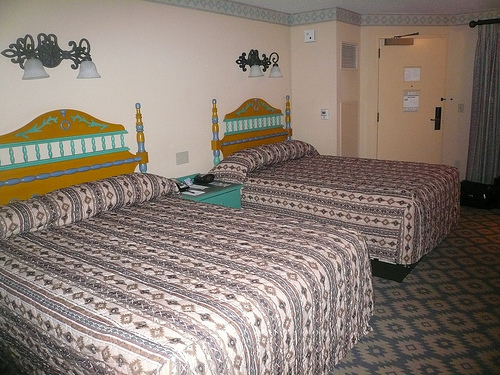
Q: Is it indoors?
A: Yes, it is indoors.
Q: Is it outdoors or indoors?
A: It is indoors.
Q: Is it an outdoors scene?
A: No, it is indoors.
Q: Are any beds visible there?
A: Yes, there is a bed.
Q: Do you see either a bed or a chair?
A: Yes, there is a bed.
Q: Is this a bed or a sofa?
A: This is a bed.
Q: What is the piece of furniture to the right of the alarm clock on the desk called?
A: The piece of furniture is a bed.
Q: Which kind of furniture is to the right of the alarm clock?
A: The piece of furniture is a bed.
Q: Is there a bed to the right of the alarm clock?
A: Yes, there is a bed to the right of the alarm clock.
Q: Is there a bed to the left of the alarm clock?
A: No, the bed is to the right of the alarm clock.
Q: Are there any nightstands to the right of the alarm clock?
A: No, there is a bed to the right of the alarm clock.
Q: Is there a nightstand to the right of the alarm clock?
A: No, there is a bed to the right of the alarm clock.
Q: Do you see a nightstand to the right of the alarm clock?
A: No, there is a bed to the right of the alarm clock.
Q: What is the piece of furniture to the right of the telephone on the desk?
A: The piece of furniture is a bed.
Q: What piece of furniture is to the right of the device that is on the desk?
A: The piece of furniture is a bed.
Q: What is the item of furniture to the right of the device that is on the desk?
A: The piece of furniture is a bed.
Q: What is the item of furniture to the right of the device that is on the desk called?
A: The piece of furniture is a bed.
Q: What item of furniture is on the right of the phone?
A: The piece of furniture is a bed.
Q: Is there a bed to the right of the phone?
A: Yes, there is a bed to the right of the phone.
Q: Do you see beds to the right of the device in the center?
A: Yes, there is a bed to the right of the phone.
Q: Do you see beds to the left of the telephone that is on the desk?
A: No, the bed is to the right of the telephone.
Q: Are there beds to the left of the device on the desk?
A: No, the bed is to the right of the telephone.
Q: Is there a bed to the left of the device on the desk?
A: No, the bed is to the right of the telephone.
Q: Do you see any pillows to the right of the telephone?
A: No, there is a bed to the right of the telephone.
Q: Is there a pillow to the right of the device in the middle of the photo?
A: No, there is a bed to the right of the telephone.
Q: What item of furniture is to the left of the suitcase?
A: The piece of furniture is a bed.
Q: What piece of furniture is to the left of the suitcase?
A: The piece of furniture is a bed.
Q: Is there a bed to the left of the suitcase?
A: Yes, there is a bed to the left of the suitcase.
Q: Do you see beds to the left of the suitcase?
A: Yes, there is a bed to the left of the suitcase.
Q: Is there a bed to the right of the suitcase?
A: No, the bed is to the left of the suitcase.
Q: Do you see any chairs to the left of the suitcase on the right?
A: No, there is a bed to the left of the suitcase.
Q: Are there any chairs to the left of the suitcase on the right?
A: No, there is a bed to the left of the suitcase.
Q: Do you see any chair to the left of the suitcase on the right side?
A: No, there is a bed to the left of the suitcase.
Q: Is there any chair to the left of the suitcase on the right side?
A: No, there is a bed to the left of the suitcase.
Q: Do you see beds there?
A: Yes, there is a bed.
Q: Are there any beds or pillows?
A: Yes, there is a bed.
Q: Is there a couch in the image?
A: No, there are no couches.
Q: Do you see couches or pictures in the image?
A: No, there are no couches or pictures.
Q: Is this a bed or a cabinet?
A: This is a bed.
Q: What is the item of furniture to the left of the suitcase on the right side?
A: The piece of furniture is a bed.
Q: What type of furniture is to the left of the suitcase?
A: The piece of furniture is a bed.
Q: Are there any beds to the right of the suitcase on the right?
A: No, the bed is to the left of the suitcase.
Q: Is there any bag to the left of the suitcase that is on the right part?
A: No, there is a bed to the left of the suitcase.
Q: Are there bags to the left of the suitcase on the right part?
A: No, there is a bed to the left of the suitcase.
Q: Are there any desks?
A: Yes, there is a desk.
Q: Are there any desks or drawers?
A: Yes, there is a desk.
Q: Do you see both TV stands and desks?
A: No, there is a desk but no TV stands.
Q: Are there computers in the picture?
A: No, there are no computers.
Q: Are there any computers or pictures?
A: No, there are no computers or pictures.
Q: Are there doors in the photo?
A: Yes, there is a door.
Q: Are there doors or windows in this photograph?
A: Yes, there is a door.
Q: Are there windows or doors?
A: Yes, there is a door.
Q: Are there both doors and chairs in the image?
A: No, there is a door but no chairs.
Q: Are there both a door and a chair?
A: No, there is a door but no chairs.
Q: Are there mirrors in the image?
A: No, there are no mirrors.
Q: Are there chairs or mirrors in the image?
A: No, there are no mirrors or chairs.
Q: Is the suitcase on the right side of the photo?
A: Yes, the suitcase is on the right of the image.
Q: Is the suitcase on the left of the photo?
A: No, the suitcase is on the right of the image.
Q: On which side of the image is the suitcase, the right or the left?
A: The suitcase is on the right of the image.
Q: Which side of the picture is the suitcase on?
A: The suitcase is on the right of the image.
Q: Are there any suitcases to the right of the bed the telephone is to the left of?
A: Yes, there is a suitcase to the right of the bed.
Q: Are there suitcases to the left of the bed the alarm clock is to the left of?
A: No, the suitcase is to the right of the bed.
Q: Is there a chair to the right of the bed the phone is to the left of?
A: No, there is a suitcase to the right of the bed.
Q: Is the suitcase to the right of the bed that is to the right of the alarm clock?
A: Yes, the suitcase is to the right of the bed.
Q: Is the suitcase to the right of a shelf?
A: No, the suitcase is to the right of the bed.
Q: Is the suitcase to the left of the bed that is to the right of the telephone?
A: No, the suitcase is to the right of the bed.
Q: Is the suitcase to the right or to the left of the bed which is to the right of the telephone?
A: The suitcase is to the right of the bed.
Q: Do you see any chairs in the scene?
A: No, there are no chairs.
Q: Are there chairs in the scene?
A: No, there are no chairs.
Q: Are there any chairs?
A: No, there are no chairs.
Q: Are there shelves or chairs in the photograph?
A: No, there are no chairs or shelves.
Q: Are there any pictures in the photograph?
A: No, there are no pictures.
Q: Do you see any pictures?
A: No, there are no pictures.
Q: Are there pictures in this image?
A: No, there are no pictures.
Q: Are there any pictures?
A: No, there are no pictures.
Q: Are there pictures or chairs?
A: No, there are no pictures or chairs.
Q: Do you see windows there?
A: Yes, there is a window.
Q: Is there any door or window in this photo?
A: Yes, there is a window.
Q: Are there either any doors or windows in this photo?
A: Yes, there is a window.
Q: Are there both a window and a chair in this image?
A: No, there is a window but no chairs.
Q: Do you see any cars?
A: No, there are no cars.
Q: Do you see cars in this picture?
A: No, there are no cars.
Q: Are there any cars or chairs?
A: No, there are no cars or chairs.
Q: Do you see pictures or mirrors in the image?
A: No, there are no pictures or mirrors.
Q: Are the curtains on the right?
A: Yes, the curtains are on the right of the image.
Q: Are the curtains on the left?
A: No, the curtains are on the right of the image.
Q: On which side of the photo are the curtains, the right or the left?
A: The curtains are on the right of the image.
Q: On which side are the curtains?
A: The curtains are on the right of the image.